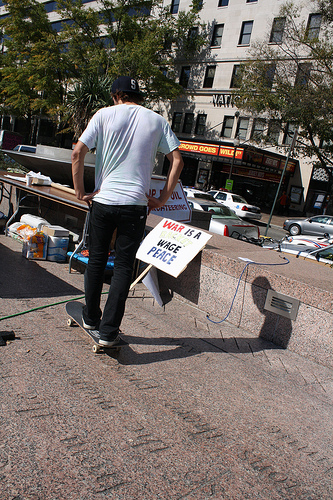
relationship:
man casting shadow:
[76, 74, 184, 345] [118, 269, 292, 366]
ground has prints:
[29, 388, 246, 487] [75, 382, 217, 461]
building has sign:
[139, 9, 327, 201] [177, 141, 243, 159]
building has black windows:
[139, 9, 327, 201] [182, 67, 256, 94]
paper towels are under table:
[47, 237, 70, 265] [1, 166, 89, 263]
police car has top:
[208, 186, 260, 222] [209, 181, 241, 196]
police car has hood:
[208, 186, 260, 222] [192, 187, 209, 196]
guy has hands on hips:
[76, 74, 184, 345] [68, 145, 181, 205]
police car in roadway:
[208, 186, 260, 222] [227, 209, 294, 239]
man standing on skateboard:
[76, 74, 184, 345] [60, 294, 131, 359]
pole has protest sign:
[129, 261, 152, 296] [138, 216, 211, 276]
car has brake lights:
[194, 189, 265, 241] [222, 222, 261, 238]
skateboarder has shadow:
[76, 74, 184, 345] [118, 269, 292, 366]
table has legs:
[1, 166, 89, 263] [7, 195, 92, 269]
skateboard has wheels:
[60, 294, 131, 359] [64, 317, 100, 362]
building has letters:
[139, 9, 327, 201] [207, 92, 244, 108]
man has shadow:
[76, 74, 184, 345] [118, 269, 292, 366]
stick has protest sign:
[129, 261, 152, 296] [138, 216, 211, 276]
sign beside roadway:
[157, 183, 193, 226] [238, 209, 294, 247]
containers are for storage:
[47, 222, 70, 265] [37, 224, 69, 238]